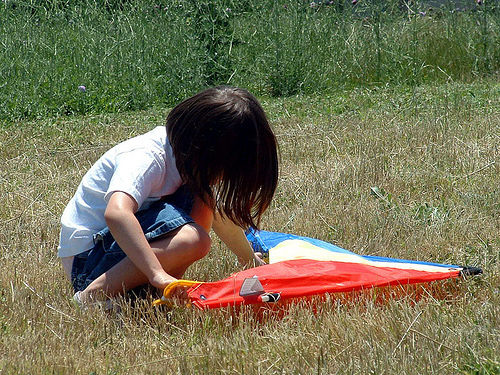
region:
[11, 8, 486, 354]
little girl in a field with her kite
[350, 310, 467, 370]
long brown grass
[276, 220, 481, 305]
multi-colored kite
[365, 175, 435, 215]
dandelions growing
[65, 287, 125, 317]
girl's white sneaker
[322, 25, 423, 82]
grass and bushes at field's edge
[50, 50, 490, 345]
girl bent down attending to her toy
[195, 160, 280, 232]
hair fallen down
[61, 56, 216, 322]
little girl in a blue jean skirt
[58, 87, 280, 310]
A little girl bending down with dark brown hair.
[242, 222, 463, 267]
Blue section of the kite.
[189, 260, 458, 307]
Red section of the kite.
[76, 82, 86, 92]
The head of a purple flower in the greener grass.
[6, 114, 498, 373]
Brown dead grass all around the girl.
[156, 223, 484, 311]
A red, white and blue kite.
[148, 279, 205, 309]
The yellow string holder/handle for the kite.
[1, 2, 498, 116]
The taller greener grass.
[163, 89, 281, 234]
Dark brown hair hanging all around a girl's face.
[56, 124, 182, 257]
A white t-shirt on a girl.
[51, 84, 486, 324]
A young girl with a kite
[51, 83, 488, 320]
A young girl with a kite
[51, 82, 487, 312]
A young girl with a kite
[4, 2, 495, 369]
a child is working on a kite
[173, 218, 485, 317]
the kite is on the ground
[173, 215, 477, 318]
the kite is red, white, and blue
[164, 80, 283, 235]
the girl has long black hair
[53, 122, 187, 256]
the t-shirt is white on the child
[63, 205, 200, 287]
blue jeans are on the girl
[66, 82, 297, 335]
the girl is kneeling down to fix the kite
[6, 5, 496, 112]
the grass is high along the fenceline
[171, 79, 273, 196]
head of a person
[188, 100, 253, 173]
hair of a person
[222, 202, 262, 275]
arm of a person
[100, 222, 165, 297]
arm of a person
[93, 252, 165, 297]
leg of a person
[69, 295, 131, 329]
feet of a person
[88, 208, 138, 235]
elbow of a person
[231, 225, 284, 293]
hand of a person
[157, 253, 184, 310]
hand of a person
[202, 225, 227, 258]
knee of a person